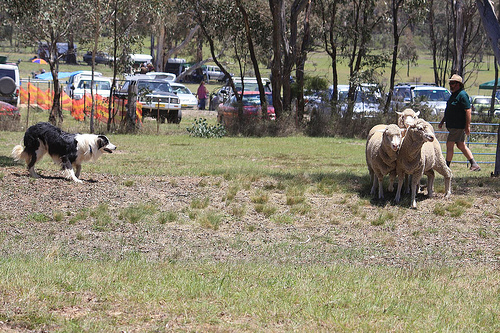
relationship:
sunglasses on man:
[447, 72, 465, 94] [439, 74, 481, 171]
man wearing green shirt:
[439, 74, 481, 171] [442, 89, 472, 129]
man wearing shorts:
[439, 74, 481, 171] [440, 119, 476, 149]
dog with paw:
[9, 122, 119, 184] [65, 171, 83, 185]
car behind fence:
[66, 71, 114, 101] [14, 80, 481, 141]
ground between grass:
[1, 128, 497, 331] [0, 105, 500, 330]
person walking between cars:
[191, 75, 213, 114] [81, 70, 419, 123]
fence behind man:
[423, 120, 497, 163] [439, 74, 481, 171]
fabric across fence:
[22, 81, 145, 128] [16, 82, 166, 126]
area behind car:
[0, 135, 500, 333] [393, 81, 455, 126]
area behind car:
[0, 135, 500, 333] [297, 86, 376, 136]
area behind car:
[0, 135, 500, 333] [215, 90, 280, 130]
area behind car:
[0, 135, 500, 333] [111, 79, 180, 116]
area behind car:
[0, 135, 500, 333] [66, 71, 118, 101]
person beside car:
[191, 75, 213, 114] [169, 78, 199, 113]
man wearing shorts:
[439, 74, 481, 171] [447, 125, 466, 142]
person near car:
[191, 75, 213, 114] [168, 72, 198, 114]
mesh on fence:
[12, 86, 140, 126] [20, 61, 123, 124]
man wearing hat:
[439, 74, 481, 171] [418, 50, 480, 190]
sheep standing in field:
[364, 120, 403, 204] [205, 197, 291, 255]